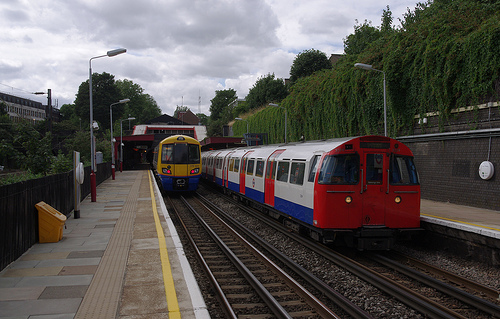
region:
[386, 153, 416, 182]
window on a bus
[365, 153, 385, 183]
window on a bus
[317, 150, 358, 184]
window on a bus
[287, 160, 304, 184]
window on a bus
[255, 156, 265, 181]
window on a bus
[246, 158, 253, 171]
window on a bus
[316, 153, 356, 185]
window on a train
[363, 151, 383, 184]
window on a train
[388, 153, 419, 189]
window on a train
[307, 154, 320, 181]
window on a train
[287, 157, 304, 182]
window on a train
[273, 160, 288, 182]
window on a train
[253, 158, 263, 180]
window on a train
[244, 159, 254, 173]
window on a train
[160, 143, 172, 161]
window on a train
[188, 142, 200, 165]
window on a train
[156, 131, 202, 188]
a yellow and blue train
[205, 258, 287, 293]
a set of train tracks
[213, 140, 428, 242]
a red,white and blue train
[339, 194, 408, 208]
headlights on a train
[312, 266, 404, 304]
gravel between train tracks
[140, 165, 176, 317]
a yellow line painted on a plateform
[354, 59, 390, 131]
a security light on a plateform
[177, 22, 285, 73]
white clouds in the sky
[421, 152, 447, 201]
a brick wall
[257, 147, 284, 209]
red doors on a train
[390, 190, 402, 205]
light on a train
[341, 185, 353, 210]
light on a train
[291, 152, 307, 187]
window on a train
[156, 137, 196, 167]
window on a train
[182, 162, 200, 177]
light on a train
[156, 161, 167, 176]
light on a train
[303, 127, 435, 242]
train on a track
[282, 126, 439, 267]
The backend of a train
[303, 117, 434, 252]
The red backend of a train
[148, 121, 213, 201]
The yellow backend of a train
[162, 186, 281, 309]
Railroad tracks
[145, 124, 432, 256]
Two trains on a track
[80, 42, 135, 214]
A light pole on the sidewalk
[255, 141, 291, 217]
A red door to the train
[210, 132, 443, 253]
A red white and blue train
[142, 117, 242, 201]
A yellow train next to another train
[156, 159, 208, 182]
The brake lights of the train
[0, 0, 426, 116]
clouds in daytime sky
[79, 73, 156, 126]
green leaves on trees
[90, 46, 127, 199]
light on curved pole